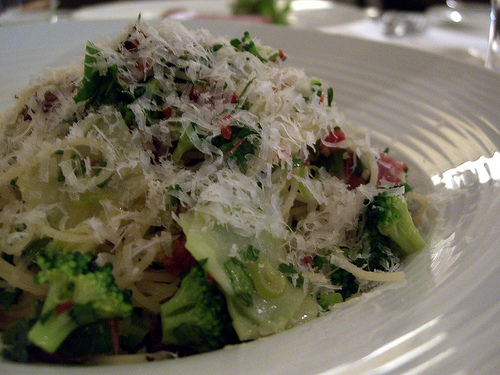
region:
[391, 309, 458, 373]
this is a plate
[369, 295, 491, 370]
the plate is round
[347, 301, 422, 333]
the plate is white in color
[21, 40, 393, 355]
this is some food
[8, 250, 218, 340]
this is the broccolli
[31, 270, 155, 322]
the broccolli is green in color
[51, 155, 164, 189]
these are some shreddings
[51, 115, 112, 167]
the shreddings are white in color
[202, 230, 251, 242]
this is some lettuce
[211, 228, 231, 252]
the lettuce is big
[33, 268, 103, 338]
this is a broccoli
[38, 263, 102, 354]
the broccoli is green in color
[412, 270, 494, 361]
this is a plate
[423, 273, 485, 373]
the plate is white in color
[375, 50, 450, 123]
the plate is round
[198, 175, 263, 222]
salad is on the food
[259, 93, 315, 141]
the salad is white in color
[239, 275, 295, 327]
the food is yummy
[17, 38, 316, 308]
the plate is full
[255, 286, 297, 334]
the food is creamy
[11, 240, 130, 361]
peice of food on a plate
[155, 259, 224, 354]
peice of food on a plate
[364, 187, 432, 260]
peice of food on a plate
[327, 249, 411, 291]
peice of food on a plate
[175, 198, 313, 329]
peice of food on a plate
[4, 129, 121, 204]
peice of food on a plate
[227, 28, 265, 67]
peice of food on a plate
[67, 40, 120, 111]
peice of food on a plate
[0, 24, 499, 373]
large white plate full of food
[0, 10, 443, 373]
food with cheese on top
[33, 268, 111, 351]
green broccoli in plate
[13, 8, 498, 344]
round white plate under food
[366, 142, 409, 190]
red tomato on plate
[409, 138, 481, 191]
light reflecting off plate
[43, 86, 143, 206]
small noodles on broccoli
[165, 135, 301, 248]
white topping on broccoli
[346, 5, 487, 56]
glasses on table in background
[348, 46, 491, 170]
small ridges on plate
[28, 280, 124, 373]
green stem of broccoli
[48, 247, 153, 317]
green head of broccoli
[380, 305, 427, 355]
Ripples on white plate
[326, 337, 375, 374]
Ripples on white plate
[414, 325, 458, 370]
Ripples on white plate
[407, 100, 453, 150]
Ripples on white plate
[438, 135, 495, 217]
Ripples on white plate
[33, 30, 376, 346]
Food on white plate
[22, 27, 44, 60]
Ripples on white plate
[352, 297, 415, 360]
Ripples on white plate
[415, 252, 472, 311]
Ripples on white plate